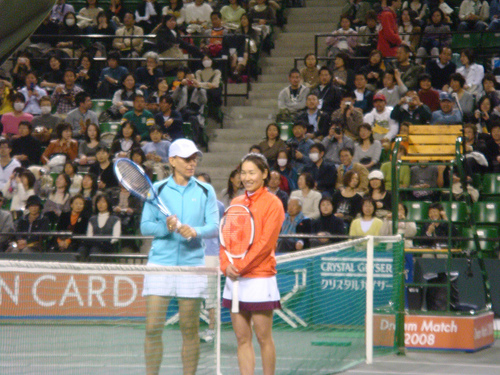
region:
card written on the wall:
[30, 270, 133, 311]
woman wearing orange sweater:
[217, 153, 288, 373]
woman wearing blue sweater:
[137, 137, 218, 372]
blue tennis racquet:
[110, 155, 195, 235]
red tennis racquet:
[217, 205, 252, 310]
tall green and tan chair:
[391, 123, 459, 313]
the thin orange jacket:
[220, 185, 283, 276]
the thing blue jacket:
[137, 175, 217, 265]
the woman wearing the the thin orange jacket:
[220, 148, 281, 371]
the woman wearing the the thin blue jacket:
[142, 139, 218, 372]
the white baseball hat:
[169, 136, 204, 158]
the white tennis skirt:
[140, 263, 211, 301]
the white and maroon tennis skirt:
[220, 275, 281, 313]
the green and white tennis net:
[0, 234, 404, 372]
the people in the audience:
[0, 0, 495, 266]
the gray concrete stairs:
[118, 0, 353, 265]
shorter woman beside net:
[215, 147, 295, 374]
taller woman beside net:
[128, 133, 222, 373]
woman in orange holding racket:
[213, 202, 258, 316]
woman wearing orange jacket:
[218, 189, 283, 283]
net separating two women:
[0, 228, 408, 373]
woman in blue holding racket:
[112, 152, 196, 248]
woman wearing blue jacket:
[135, 171, 224, 267]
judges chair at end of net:
[381, 113, 493, 316]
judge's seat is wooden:
[395, 118, 462, 170]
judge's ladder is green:
[387, 132, 494, 320]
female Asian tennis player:
[216, 149, 285, 374]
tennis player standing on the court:
[111, 138, 218, 374]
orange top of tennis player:
[220, 188, 281, 278]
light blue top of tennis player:
[140, 175, 217, 265]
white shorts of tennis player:
[140, 262, 205, 297]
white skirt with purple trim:
[220, 275, 280, 310]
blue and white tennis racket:
[115, 157, 192, 242]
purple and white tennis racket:
[218, 204, 255, 314]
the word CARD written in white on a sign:
[31, 271, 136, 310]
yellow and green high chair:
[392, 122, 492, 316]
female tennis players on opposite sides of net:
[107, 130, 289, 372]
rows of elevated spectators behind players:
[5, 9, 495, 311]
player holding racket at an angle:
[112, 134, 220, 265]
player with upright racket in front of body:
[214, 148, 286, 318]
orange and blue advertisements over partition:
[4, 246, 396, 325]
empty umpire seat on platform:
[367, 112, 494, 352]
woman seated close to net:
[344, 195, 389, 245]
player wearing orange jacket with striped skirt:
[220, 152, 285, 314]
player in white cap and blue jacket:
[140, 134, 220, 267]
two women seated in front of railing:
[60, 190, 122, 245]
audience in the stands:
[30, 78, 150, 223]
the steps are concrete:
[210, 122, 250, 187]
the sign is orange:
[12, 271, 157, 308]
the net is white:
[278, 241, 408, 338]